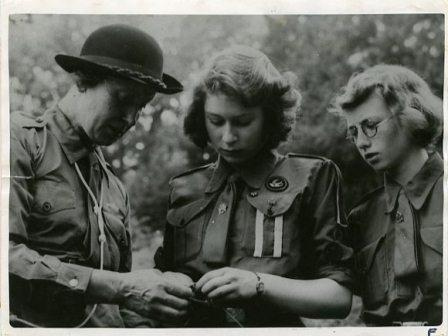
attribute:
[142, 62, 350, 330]
woman — looking 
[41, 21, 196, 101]
trilbyhat — woman's head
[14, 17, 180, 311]
man — Dark hat 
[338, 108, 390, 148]
glasses —  blonde woman's face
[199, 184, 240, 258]
tie —  light haired woman's shirt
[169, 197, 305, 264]
pocket — two white stripes 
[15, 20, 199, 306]
man — hat 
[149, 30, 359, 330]
woman — Brown haired 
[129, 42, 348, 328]
woman — Light haired 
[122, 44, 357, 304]
woman —  standing outside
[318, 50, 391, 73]
leaves —  tree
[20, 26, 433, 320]
scene —  outside 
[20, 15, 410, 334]
scene —  outside 